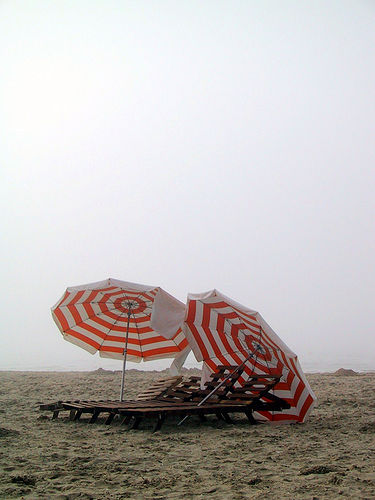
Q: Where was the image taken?
A: It was taken at the beach.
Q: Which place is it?
A: It is a beach.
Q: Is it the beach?
A: Yes, it is the beach.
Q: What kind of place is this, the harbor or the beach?
A: It is the beach.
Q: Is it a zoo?
A: No, it is a beach.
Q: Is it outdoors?
A: Yes, it is outdoors.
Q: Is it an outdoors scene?
A: Yes, it is outdoors.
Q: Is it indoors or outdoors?
A: It is outdoors.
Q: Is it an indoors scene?
A: No, it is outdoors.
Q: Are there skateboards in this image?
A: No, there are no skateboards.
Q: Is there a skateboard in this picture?
A: No, there are no skateboards.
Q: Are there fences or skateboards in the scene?
A: No, there are no skateboards or fences.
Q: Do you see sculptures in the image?
A: No, there are no sculptures.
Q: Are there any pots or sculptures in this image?
A: No, there are no sculptures or pots.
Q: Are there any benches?
A: Yes, there is a bench.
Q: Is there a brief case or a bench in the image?
A: Yes, there is a bench.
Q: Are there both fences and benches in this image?
A: No, there is a bench but no fences.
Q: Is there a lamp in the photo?
A: No, there are no lamps.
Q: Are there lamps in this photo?
A: No, there are no lamps.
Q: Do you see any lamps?
A: No, there are no lamps.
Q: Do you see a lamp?
A: No, there are no lamps.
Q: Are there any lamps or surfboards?
A: No, there are no lamps or surfboards.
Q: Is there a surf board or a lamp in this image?
A: No, there are no lamps or surfboards.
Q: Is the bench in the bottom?
A: Yes, the bench is in the bottom of the image.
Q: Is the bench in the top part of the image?
A: No, the bench is in the bottom of the image.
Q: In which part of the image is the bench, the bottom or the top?
A: The bench is in the bottom of the image.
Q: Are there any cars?
A: No, there are no cars.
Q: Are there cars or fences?
A: No, there are no cars or fences.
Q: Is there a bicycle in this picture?
A: No, there are no bicycles.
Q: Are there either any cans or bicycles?
A: No, there are no bicycles or cans.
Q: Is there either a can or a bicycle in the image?
A: No, there are no bicycles or cans.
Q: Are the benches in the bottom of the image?
A: Yes, the benches are in the bottom of the image.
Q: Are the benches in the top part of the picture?
A: No, the benches are in the bottom of the image.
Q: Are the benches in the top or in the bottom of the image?
A: The benches are in the bottom of the image.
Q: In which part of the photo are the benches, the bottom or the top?
A: The benches are in the bottom of the image.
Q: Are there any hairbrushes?
A: No, there are no hairbrushes.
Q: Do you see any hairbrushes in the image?
A: No, there are no hairbrushes.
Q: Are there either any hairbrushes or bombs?
A: No, there are no hairbrushes or bombs.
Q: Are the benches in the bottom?
A: Yes, the benches are in the bottom of the image.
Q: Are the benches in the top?
A: No, the benches are in the bottom of the image.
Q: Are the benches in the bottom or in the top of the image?
A: The benches are in the bottom of the image.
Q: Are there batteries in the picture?
A: No, there are no batteries.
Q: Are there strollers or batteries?
A: No, there are no batteries or strollers.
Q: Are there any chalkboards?
A: No, there are no chalkboards.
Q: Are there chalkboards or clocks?
A: No, there are no chalkboards or clocks.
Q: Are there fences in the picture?
A: No, there are no fences.